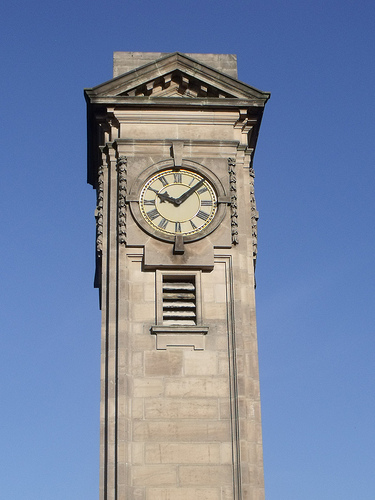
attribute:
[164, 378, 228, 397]
stone — lines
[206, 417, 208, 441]
line — vertical, horizontal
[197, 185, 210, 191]
two — roman, numeral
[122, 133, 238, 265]
four keystones — quarter, hour, marks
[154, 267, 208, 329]
window — small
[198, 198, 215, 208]
roman numeral — three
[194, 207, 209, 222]
number 4 — roman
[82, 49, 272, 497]
clock tower — tall, grey, concrete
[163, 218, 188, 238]
numeral — roman numeral, five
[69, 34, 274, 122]
edging — dark, gray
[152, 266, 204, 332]
slats — rectangle, horizontal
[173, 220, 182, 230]
six — roman, numeral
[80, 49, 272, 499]
building — stone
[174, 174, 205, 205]
minute hand — black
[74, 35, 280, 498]
tower — side, stone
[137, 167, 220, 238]
face — clock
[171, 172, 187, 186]
numeral — roman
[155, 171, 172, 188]
numeral — roman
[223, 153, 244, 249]
decoration — stone, carved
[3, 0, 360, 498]
sky — blue, cloudless